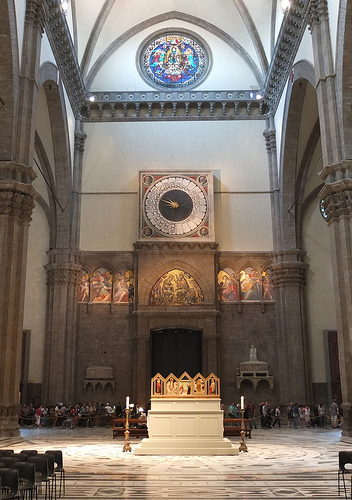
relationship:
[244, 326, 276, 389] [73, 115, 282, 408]
statue near wall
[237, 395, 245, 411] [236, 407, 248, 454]
candle on holder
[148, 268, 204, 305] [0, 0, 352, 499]
painting of building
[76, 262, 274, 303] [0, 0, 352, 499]
paintings in middle of building